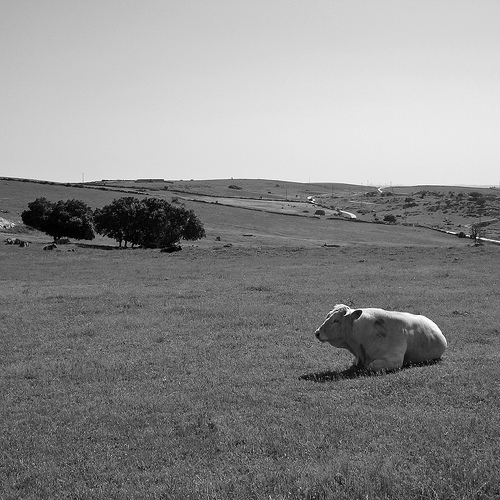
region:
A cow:
[289, 264, 488, 399]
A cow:
[341, 270, 422, 405]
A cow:
[277, 250, 356, 417]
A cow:
[339, 316, 473, 487]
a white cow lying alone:
[311, 291, 451, 383]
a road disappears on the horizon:
[317, 178, 494, 250]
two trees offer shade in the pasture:
[23, 195, 203, 256]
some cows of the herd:
[1, 220, 195, 267]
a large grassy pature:
[17, 239, 306, 495]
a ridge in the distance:
[106, 165, 499, 213]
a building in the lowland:
[301, 191, 324, 208]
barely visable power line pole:
[73, 168, 94, 187]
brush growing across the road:
[353, 188, 498, 233]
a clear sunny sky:
[7, 10, 499, 170]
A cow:
[281, 236, 381, 483]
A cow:
[311, 236, 410, 435]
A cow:
[341, 206, 450, 430]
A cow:
[379, 270, 473, 352]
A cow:
[249, 202, 431, 383]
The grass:
[226, 401, 317, 482]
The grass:
[249, 439, 313, 497]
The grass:
[226, 358, 296, 468]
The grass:
[263, 413, 330, 488]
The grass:
[296, 429, 358, 496]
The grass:
[184, 386, 297, 463]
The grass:
[268, 394, 320, 446]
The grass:
[284, 373, 351, 468]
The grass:
[267, 461, 300, 491]